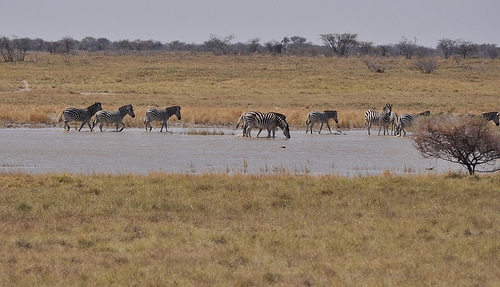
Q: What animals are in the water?
A: Zebras.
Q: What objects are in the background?
A: Trees.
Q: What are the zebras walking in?
A: Water.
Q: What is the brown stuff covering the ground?
A: Grass.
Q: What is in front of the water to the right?
A: A tree.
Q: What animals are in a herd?
A: Zebras.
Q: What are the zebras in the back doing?
A: Walking.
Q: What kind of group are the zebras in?
A: A herd.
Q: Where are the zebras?
A: At a watering hole.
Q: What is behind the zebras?
A: A plain of grass.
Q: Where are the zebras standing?
A: In the water.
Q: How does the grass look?
A: Dry.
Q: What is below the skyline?
A: Trees.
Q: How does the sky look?
A: Cloudy.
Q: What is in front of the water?
A: Brown grass.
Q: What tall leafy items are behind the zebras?
A: Trees.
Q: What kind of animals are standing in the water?
A: Zebras.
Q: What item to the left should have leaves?
A: A tree.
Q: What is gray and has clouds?
A: Sky.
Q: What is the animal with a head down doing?
A: Drinking water.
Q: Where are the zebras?
A: In the water.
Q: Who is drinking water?
A: A zebra.